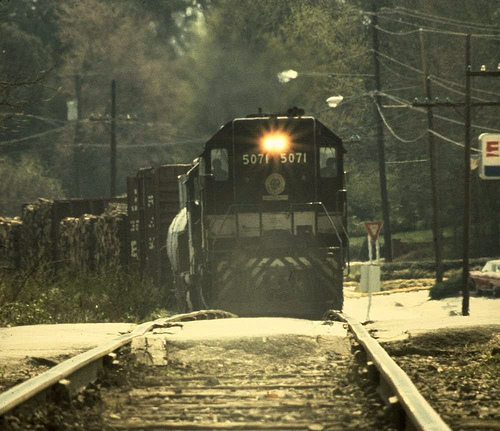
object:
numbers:
[242, 151, 250, 165]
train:
[1, 106, 351, 317]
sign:
[478, 129, 499, 183]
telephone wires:
[368, 3, 497, 30]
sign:
[362, 220, 384, 242]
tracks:
[1, 309, 460, 430]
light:
[258, 130, 292, 156]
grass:
[2, 251, 165, 321]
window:
[318, 146, 340, 180]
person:
[211, 158, 228, 181]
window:
[210, 147, 230, 183]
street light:
[277, 68, 300, 86]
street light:
[324, 94, 345, 109]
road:
[2, 314, 496, 416]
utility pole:
[72, 73, 79, 202]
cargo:
[56, 203, 126, 284]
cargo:
[23, 199, 55, 291]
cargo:
[1, 215, 18, 281]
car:
[467, 259, 500, 298]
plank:
[123, 384, 337, 398]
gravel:
[87, 352, 167, 431]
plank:
[104, 419, 365, 430]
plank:
[146, 400, 348, 412]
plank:
[129, 336, 168, 367]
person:
[320, 155, 339, 178]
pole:
[108, 77, 116, 200]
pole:
[371, 7, 393, 279]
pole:
[427, 76, 443, 288]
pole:
[460, 32, 474, 318]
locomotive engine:
[185, 113, 351, 318]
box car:
[126, 162, 195, 300]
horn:
[285, 105, 306, 119]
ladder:
[204, 204, 243, 292]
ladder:
[308, 194, 351, 279]